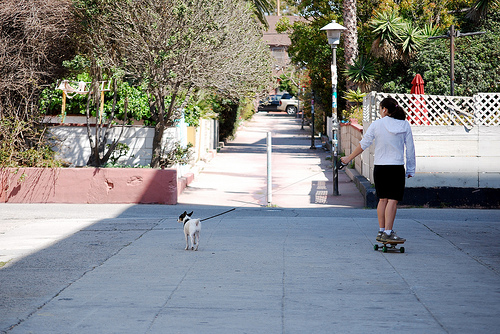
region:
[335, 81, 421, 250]
person wearing white hoodie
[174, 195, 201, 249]
dog on a street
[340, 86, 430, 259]
person wearing black shorts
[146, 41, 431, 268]
person walking a dog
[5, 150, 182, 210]
a small brick wall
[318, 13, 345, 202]
a street lamp post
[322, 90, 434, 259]
person on a skateboard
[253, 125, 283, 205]
a steel pole on ground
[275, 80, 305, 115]
rear of a sedan car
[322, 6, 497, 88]
bunch of trees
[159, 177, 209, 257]
Dog on the sidewalk.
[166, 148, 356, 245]
The dog is on a leash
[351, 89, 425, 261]
The person is skateboarding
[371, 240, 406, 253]
Wheels on the skateboard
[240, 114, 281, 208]
Pole in the middle of sidewalk.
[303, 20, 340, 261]
Street light on the sidewalk.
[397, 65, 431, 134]
Red umbrella in the yard.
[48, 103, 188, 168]
A white building in the yard.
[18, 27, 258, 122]
The tree in the yard.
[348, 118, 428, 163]
The person is wearing a white hoodie.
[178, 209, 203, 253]
white and brown dog on leash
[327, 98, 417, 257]
young person on skateboard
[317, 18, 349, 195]
street light in alley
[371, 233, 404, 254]
skateboard being ridden by young person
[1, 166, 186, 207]
red concrete wall beside street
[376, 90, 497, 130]
lattice atop wooden fence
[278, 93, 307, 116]
rear of car on street at end of alley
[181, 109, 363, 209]
alley between two streets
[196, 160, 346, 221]
leash on dog pulling person on skateboard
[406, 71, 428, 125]
red market umbrella folded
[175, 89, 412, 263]
a woman walking a dog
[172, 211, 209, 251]
a small white dog with black ears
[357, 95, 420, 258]
a woman on a skateboard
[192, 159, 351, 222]
a retractable leash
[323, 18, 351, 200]
a lamppost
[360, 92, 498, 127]
white lattice on top of a wall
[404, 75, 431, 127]
a folded up red umbrella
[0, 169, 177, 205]
a short red concrete wall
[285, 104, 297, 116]
the back tire of a car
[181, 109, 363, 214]
a large concrete walkway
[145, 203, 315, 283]
the dog is on a leash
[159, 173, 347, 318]
the leash is black and white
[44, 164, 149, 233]
the brick is red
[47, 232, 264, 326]
the ground is made of cement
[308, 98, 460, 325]
the woman is on a skateboard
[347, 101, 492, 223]
the woman is wearing a hoodie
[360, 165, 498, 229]
the woman is wearing black shorts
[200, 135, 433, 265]
sun is shining on the ground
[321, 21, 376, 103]
a light pole is standing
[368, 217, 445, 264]
the woman is wearing white socks